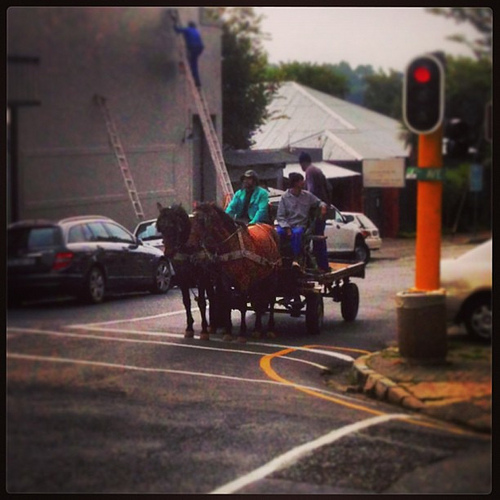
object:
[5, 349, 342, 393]
line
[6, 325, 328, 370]
line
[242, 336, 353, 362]
line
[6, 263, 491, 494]
pavement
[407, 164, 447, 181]
street sign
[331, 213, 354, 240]
ground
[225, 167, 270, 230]
man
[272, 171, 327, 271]
man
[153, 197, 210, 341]
horse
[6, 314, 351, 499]
road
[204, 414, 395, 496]
line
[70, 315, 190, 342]
line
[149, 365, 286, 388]
line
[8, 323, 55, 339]
line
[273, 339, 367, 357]
line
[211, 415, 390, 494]
line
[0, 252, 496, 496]
street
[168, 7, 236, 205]
ladder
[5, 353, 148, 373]
white line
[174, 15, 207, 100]
man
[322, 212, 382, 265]
jeep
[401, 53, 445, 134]
light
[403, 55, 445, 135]
pole light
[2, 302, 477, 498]
sidewalk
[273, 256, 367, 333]
carriage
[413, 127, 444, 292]
pole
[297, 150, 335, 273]
man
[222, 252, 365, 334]
cart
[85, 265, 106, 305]
tire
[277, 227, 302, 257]
blue pants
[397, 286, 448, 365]
trash can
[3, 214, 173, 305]
car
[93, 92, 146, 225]
ladder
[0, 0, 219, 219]
building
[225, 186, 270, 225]
coat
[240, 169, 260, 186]
hat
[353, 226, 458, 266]
sidewalk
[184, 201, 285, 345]
horse